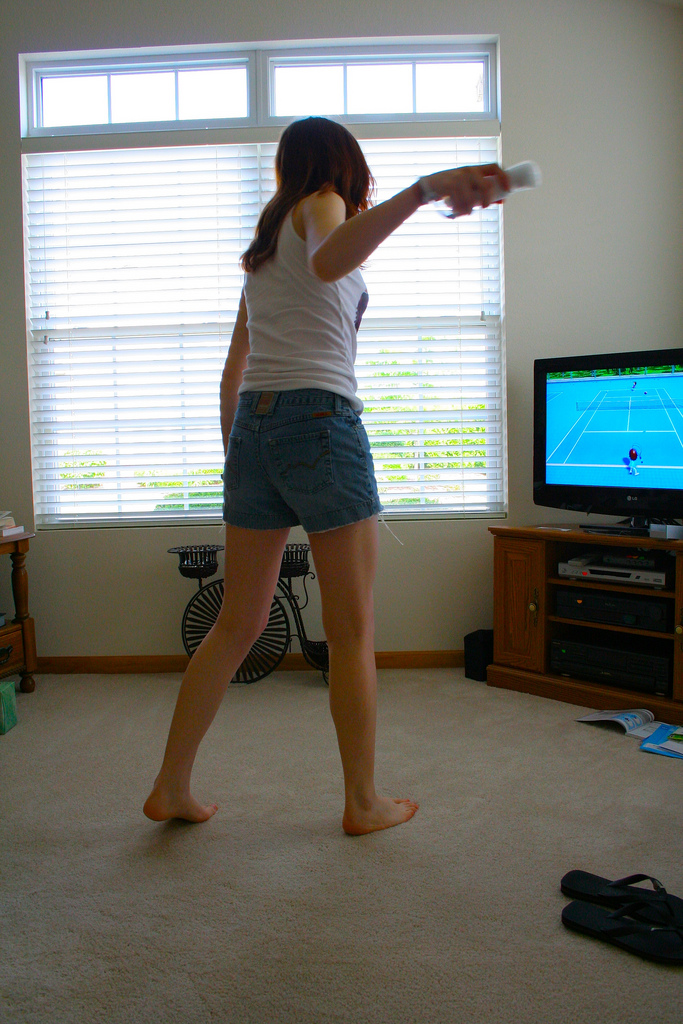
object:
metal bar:
[207, 587, 221, 609]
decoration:
[166, 544, 330, 687]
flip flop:
[559, 869, 683, 930]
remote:
[431, 158, 543, 219]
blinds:
[21, 119, 510, 532]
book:
[573, 709, 679, 739]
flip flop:
[562, 901, 683, 971]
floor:
[0, 673, 682, 1023]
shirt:
[237, 204, 370, 418]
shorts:
[219, 388, 405, 548]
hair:
[237, 117, 377, 274]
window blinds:
[18, 118, 508, 531]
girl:
[143, 117, 511, 837]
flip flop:
[560, 868, 683, 966]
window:
[16, 34, 500, 138]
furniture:
[167, 543, 331, 687]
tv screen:
[545, 365, 682, 492]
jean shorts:
[217, 387, 404, 547]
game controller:
[435, 158, 544, 219]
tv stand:
[486, 524, 683, 728]